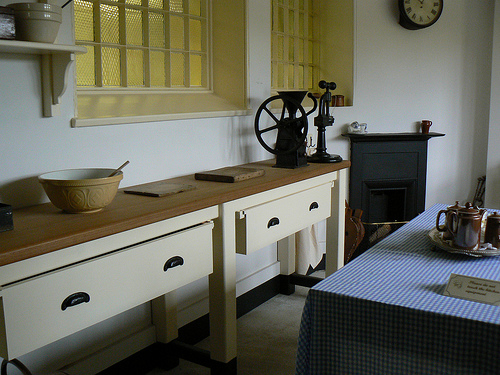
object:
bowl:
[37, 167, 122, 214]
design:
[44, 186, 117, 210]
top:
[0, 156, 350, 266]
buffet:
[4, 159, 368, 367]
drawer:
[234, 183, 334, 257]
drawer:
[4, 219, 211, 359]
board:
[194, 166, 265, 183]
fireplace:
[349, 134, 431, 242]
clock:
[392, 0, 444, 31]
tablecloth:
[298, 203, 499, 375]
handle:
[267, 217, 279, 228]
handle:
[309, 202, 319, 211]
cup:
[420, 120, 433, 134]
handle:
[429, 120, 432, 125]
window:
[72, 0, 210, 93]